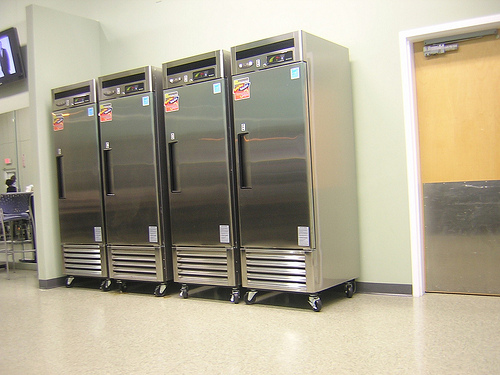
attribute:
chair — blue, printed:
[0, 192, 34, 278]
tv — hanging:
[2, 23, 24, 79]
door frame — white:
[398, 10, 498, 303]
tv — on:
[1, 26, 24, 83]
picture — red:
[230, 74, 253, 104]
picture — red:
[162, 87, 182, 115]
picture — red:
[97, 103, 117, 127]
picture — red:
[51, 114, 62, 134]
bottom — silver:
[419, 179, 499, 295]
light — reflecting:
[279, 327, 300, 352]